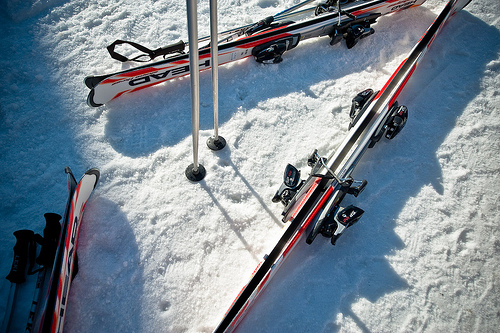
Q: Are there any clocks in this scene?
A: Yes, there is a clock.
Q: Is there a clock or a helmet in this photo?
A: Yes, there is a clock.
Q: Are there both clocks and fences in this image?
A: No, there is a clock but no fences.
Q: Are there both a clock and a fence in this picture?
A: No, there is a clock but no fences.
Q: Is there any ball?
A: No, there are no balls.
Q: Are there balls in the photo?
A: No, there are no balls.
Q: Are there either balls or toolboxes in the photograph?
A: No, there are no balls or toolboxes.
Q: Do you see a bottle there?
A: No, there are no bottles.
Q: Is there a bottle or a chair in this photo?
A: No, there are no bottles or chairs.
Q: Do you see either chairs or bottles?
A: No, there are no bottles or chairs.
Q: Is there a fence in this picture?
A: No, there are no fences.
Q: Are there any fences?
A: No, there are no fences.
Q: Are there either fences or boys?
A: No, there are no fences or boys.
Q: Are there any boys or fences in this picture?
A: No, there are no fences or boys.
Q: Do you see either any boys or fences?
A: No, there are no fences or boys.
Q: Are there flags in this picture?
A: No, there are no flags.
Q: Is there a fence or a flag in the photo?
A: No, there are no flags or fences.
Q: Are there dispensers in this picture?
A: No, there are no dispensers.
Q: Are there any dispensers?
A: No, there are no dispensers.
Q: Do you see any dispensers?
A: No, there are no dispensers.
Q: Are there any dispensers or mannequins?
A: No, there are no dispensers or mannequins.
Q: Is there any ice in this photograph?
A: Yes, there is ice.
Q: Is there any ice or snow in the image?
A: Yes, there is ice.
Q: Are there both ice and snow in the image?
A: Yes, there are both ice and snow.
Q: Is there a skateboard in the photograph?
A: No, there are no skateboards.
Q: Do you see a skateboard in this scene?
A: No, there are no skateboards.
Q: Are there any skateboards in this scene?
A: No, there are no skateboards.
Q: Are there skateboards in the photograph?
A: No, there are no skateboards.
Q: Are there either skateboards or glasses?
A: No, there are no skateboards or glasses.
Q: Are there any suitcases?
A: No, there are no suitcases.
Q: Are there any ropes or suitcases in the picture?
A: No, there are no suitcases or ropes.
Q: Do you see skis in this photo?
A: Yes, there are skis.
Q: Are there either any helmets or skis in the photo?
A: Yes, there are skis.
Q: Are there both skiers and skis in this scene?
A: No, there are skis but no skiers.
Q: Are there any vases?
A: No, there are no vases.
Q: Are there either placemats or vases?
A: No, there are no vases or placemats.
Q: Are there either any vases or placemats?
A: No, there are no vases or placemats.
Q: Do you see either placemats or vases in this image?
A: No, there are no vases or placemats.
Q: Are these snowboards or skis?
A: These are skis.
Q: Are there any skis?
A: Yes, there are skis.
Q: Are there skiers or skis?
A: Yes, there are skis.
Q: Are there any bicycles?
A: No, there are no bicycles.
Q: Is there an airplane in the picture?
A: No, there are no airplanes.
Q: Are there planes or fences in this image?
A: No, there are no planes or fences.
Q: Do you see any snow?
A: Yes, there is snow.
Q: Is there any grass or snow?
A: Yes, there is snow.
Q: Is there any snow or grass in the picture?
A: Yes, there is snow.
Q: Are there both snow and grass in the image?
A: No, there is snow but no grass.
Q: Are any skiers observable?
A: No, there are no skiers.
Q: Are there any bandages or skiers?
A: No, there are no skiers or bandages.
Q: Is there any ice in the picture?
A: Yes, there is ice.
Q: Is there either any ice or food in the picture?
A: Yes, there is ice.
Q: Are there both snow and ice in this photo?
A: Yes, there are both ice and snow.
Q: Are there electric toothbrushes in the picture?
A: No, there are no electric toothbrushes.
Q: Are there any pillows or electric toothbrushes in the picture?
A: No, there are no electric toothbrushes or pillows.